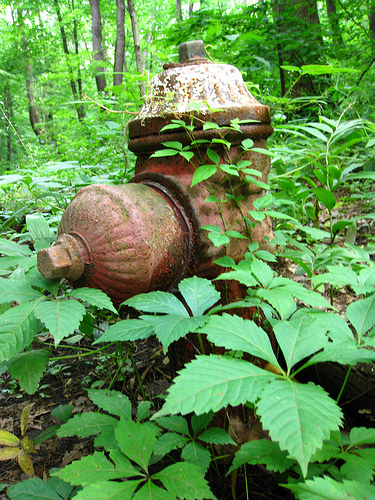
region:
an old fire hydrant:
[58, 31, 346, 457]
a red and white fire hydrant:
[43, 29, 313, 433]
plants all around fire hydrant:
[30, 108, 369, 496]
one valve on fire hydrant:
[33, 173, 193, 325]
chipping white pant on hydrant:
[122, 54, 273, 131]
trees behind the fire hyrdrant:
[22, 7, 362, 202]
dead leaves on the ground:
[2, 386, 146, 452]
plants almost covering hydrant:
[54, 78, 342, 424]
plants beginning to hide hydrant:
[42, 86, 327, 493]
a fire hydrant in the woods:
[44, 35, 357, 479]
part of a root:
[229, 433, 231, 436]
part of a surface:
[84, 358, 90, 372]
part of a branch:
[174, 476, 175, 477]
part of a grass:
[232, 448, 237, 462]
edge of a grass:
[205, 419, 217, 432]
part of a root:
[155, 467, 166, 481]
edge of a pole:
[132, 318, 152, 334]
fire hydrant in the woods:
[36, 32, 271, 341]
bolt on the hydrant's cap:
[35, 239, 68, 275]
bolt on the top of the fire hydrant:
[178, 37, 204, 60]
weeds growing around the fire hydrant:
[2, 156, 370, 498]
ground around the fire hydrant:
[14, 332, 366, 498]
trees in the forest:
[1, 5, 369, 170]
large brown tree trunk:
[270, 1, 352, 125]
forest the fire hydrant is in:
[5, 2, 371, 487]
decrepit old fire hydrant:
[38, 31, 287, 373]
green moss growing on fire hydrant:
[82, 180, 195, 303]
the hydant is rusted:
[52, 54, 367, 434]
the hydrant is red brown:
[50, 44, 325, 391]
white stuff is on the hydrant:
[164, 66, 257, 106]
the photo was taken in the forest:
[6, 8, 374, 498]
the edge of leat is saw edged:
[243, 403, 283, 451]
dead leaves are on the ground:
[25, 386, 96, 422]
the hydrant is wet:
[153, 240, 239, 295]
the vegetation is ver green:
[0, 6, 366, 495]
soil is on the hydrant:
[85, 191, 143, 262]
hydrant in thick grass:
[68, 94, 267, 398]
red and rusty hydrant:
[91, 85, 292, 379]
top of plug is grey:
[137, 60, 247, 131]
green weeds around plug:
[1, 159, 333, 479]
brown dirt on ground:
[17, 373, 125, 457]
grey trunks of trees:
[41, 8, 153, 156]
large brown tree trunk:
[277, 34, 331, 151]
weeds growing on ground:
[183, 139, 330, 259]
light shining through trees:
[13, 5, 53, 48]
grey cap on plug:
[152, 42, 214, 67]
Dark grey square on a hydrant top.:
[177, 39, 205, 62]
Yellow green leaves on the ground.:
[0, 402, 39, 478]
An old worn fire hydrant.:
[37, 38, 277, 429]